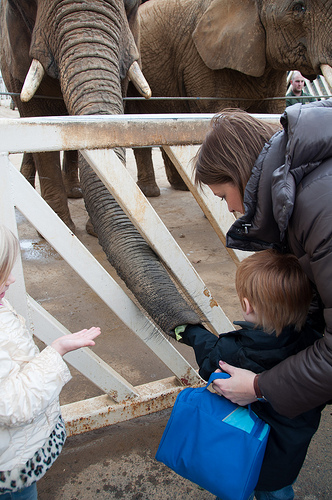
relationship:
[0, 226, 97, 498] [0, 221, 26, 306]
girl has head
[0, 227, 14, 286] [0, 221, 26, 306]
hair on head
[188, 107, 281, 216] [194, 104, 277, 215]
hair on head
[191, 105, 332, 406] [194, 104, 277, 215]
mother has head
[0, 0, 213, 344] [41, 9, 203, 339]
elephant has elephant's trunk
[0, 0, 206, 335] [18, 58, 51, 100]
elephant has tusk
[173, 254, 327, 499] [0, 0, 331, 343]
arm feeding an elephant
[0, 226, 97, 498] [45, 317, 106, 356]
girl staring at her hand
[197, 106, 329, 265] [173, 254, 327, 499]
mother helping her arm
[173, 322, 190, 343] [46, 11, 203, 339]
leaf in elephant's trunk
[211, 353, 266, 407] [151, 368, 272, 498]
hand holding lunch box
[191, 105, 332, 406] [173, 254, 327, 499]
mother with her arms around a arm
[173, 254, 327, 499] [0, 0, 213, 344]
arm feeding an elephant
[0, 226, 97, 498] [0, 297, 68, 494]
girl wearing a white coat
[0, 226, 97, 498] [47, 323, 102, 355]
girl holding out her hand